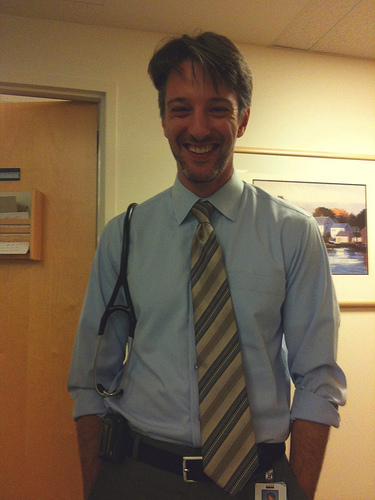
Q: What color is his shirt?
A: Blue.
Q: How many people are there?
A: One.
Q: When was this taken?
A: During the day.